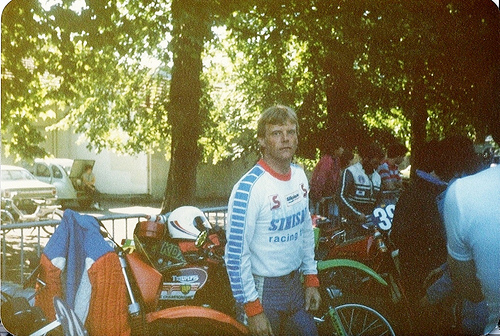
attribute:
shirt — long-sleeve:
[227, 161, 321, 316]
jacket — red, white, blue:
[38, 211, 128, 335]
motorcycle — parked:
[5, 208, 224, 336]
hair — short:
[256, 105, 299, 136]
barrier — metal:
[1, 199, 345, 307]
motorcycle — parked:
[136, 211, 231, 262]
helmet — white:
[167, 205, 214, 241]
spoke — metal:
[348, 310, 354, 336]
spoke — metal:
[361, 312, 368, 334]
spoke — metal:
[366, 323, 385, 335]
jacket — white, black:
[340, 165, 382, 234]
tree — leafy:
[156, 0, 234, 212]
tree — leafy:
[300, 0, 359, 163]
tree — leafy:
[403, 0, 437, 159]